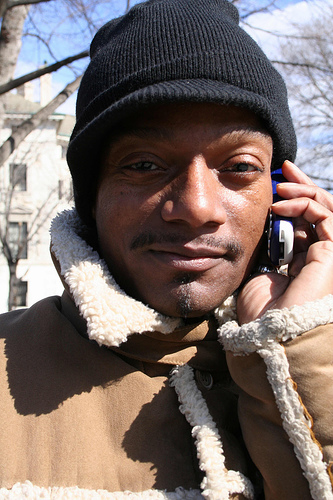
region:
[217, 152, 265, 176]
the eye of the man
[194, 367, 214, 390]
a button on the man's coat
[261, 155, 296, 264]
a blue and white cell phone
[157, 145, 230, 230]
the nose of a man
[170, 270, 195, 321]
the beard of a man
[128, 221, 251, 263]
the mustache of a man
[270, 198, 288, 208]
the man's fingernail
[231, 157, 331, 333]
the hand of a man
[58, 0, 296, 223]
a black stocking cap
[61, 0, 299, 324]
the head of a man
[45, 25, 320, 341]
a man on a cell phone.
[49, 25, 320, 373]
a man holding a cell phone.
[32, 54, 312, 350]
a man holding cell phone to his ear.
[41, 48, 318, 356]
person holding cell phone to an ear.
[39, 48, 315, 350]
person holding a cell in one hand.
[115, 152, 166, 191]
right eye of an person.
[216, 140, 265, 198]
left eye of a person.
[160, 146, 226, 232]
nose of a person.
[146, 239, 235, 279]
mouth of a person.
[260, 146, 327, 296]
left hand holding a cellular phone.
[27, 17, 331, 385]
There is a man on a cellphone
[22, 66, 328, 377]
The man has a mustache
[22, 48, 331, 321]
There are trees with no leaves in the background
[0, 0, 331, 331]
The picture was taken in the daytime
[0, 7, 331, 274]
There is a building in the background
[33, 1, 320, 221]
The man is wearing a cap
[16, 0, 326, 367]
The man is wearing a black cap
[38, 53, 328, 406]
The man is looking at the camera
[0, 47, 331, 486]
The man is wearing a coat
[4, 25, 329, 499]
The man is wearing a brown coat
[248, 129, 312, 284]
man holds cellphone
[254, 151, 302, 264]
cellphone is blue and white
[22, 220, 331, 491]
man wears insulated jacket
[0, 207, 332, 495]
insulated jacket is white and brown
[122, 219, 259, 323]
man has facial hair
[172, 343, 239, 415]
insulated jacket has button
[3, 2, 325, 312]
trees are in background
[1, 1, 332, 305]
trees are blurry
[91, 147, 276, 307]
man looks at camera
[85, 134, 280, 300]
man has smirk on face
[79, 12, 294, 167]
The black hat on the man's head.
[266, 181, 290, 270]
The cellphone in the man's hand.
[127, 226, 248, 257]
The mustache on the man's face.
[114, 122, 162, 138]
The man's left eyebrow.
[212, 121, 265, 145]
The man's right eyebrow.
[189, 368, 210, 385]
The top button on the man's coat.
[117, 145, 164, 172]
The man's left eye.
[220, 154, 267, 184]
The man's right eye.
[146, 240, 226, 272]
The lips of the man.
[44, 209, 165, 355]
The white wool collar of the coat the man is wearing.